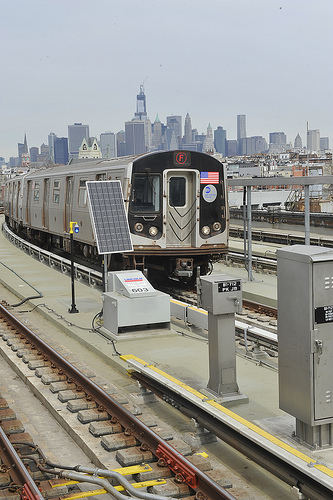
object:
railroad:
[77, 380, 142, 433]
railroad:
[114, 464, 134, 496]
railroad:
[146, 423, 193, 492]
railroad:
[136, 452, 159, 490]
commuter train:
[3, 149, 230, 288]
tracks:
[0, 217, 333, 500]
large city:
[0, 74, 333, 173]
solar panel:
[85, 179, 171, 336]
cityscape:
[13, 89, 330, 165]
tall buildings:
[67, 122, 89, 159]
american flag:
[200, 171, 220, 184]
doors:
[42, 178, 50, 231]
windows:
[52, 179, 61, 204]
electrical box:
[275, 244, 333, 452]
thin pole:
[68, 222, 80, 314]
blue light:
[74, 227, 79, 233]